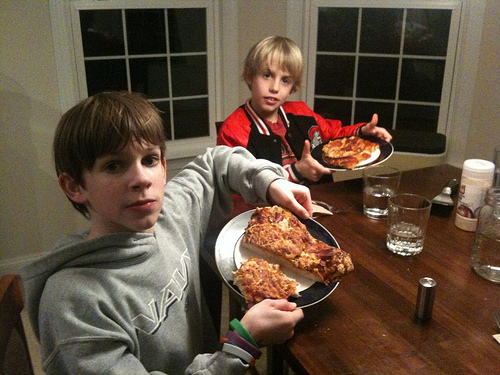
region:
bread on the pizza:
[252, 218, 322, 257]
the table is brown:
[330, 313, 389, 373]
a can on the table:
[416, 277, 438, 325]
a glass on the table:
[387, 190, 427, 253]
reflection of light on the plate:
[217, 225, 237, 263]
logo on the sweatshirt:
[120, 248, 200, 338]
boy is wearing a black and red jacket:
[224, 118, 267, 142]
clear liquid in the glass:
[387, 228, 413, 246]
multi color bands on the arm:
[224, 321, 261, 356]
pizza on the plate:
[322, 131, 374, 166]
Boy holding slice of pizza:
[237, 35, 393, 159]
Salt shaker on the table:
[407, 274, 450, 338]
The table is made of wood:
[342, 310, 375, 360]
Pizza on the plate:
[232, 194, 346, 327]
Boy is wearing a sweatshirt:
[22, 213, 219, 368]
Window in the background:
[309, 14, 462, 106]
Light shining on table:
[446, 323, 483, 373]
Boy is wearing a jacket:
[212, 88, 418, 202]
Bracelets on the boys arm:
[216, 319, 258, 359]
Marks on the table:
[355, 305, 390, 360]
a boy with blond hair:
[220, 32, 398, 214]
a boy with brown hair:
[38, 88, 313, 371]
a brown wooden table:
[228, 160, 496, 373]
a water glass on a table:
[385, 189, 432, 254]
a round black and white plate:
[212, 205, 350, 311]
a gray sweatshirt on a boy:
[17, 143, 289, 373]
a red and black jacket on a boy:
[217, 99, 369, 185]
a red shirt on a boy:
[266, 116, 304, 186]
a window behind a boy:
[299, 1, 470, 141]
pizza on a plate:
[320, 134, 378, 172]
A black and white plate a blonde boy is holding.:
[310, 128, 393, 172]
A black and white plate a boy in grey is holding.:
[214, 203, 344, 311]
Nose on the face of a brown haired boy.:
[123, 160, 149, 190]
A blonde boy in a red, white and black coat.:
[216, 32, 392, 182]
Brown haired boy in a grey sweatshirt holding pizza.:
[21, 88, 316, 372]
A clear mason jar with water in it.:
[471, 183, 499, 281]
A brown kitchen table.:
[201, 163, 498, 374]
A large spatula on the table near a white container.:
[430, 172, 458, 207]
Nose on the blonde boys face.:
[268, 73, 279, 96]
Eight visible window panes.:
[75, 8, 213, 141]